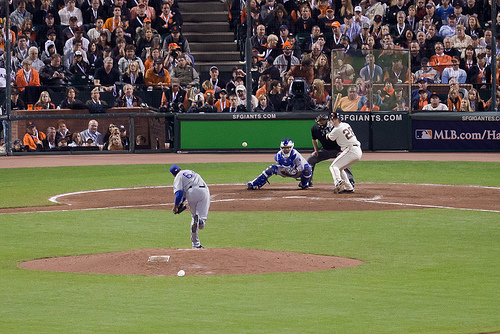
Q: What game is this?
A: Baseball.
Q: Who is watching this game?
A: The spectators.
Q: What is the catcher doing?
A: Waiting for the ball.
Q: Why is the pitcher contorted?
A: He just threw the ball.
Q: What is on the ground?
A: Sod.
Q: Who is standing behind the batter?
A: Umpire.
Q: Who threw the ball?
A: The pitcher.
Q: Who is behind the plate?
A: Catcher.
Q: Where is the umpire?
A: Behind the catcher.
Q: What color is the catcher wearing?
A: Blue.